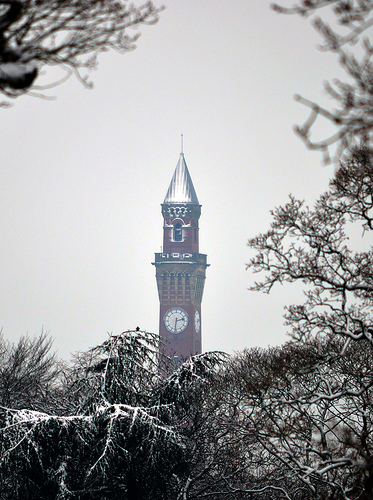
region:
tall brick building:
[140, 123, 217, 378]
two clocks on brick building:
[161, 308, 199, 339]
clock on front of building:
[157, 304, 190, 341]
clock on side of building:
[193, 307, 202, 336]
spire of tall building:
[156, 152, 203, 205]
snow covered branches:
[1, 339, 248, 499]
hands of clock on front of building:
[168, 315, 190, 334]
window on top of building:
[167, 219, 185, 250]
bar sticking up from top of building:
[179, 131, 185, 153]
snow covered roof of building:
[156, 151, 207, 198]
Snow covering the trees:
[19, 332, 244, 475]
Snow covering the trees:
[306, 254, 371, 444]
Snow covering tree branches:
[18, 377, 362, 470]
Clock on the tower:
[160, 301, 193, 331]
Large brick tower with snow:
[136, 178, 229, 337]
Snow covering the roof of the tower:
[167, 178, 213, 208]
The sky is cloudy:
[27, 226, 96, 306]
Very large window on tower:
[167, 213, 191, 247]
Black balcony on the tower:
[150, 241, 210, 269]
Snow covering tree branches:
[0, 14, 132, 36]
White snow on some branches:
[14, 392, 183, 459]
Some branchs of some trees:
[6, 353, 236, 499]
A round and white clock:
[161, 307, 190, 335]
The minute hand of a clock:
[173, 317, 178, 331]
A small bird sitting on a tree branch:
[131, 323, 142, 335]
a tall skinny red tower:
[143, 128, 216, 383]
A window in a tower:
[170, 219, 185, 242]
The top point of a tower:
[172, 131, 192, 159]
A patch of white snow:
[109, 401, 127, 416]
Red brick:
[165, 240, 192, 253]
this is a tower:
[145, 156, 215, 335]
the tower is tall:
[140, 134, 210, 339]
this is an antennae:
[173, 127, 188, 148]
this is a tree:
[81, 369, 287, 484]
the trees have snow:
[46, 365, 173, 460]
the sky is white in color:
[30, 144, 133, 276]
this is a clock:
[163, 306, 189, 331]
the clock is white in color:
[160, 306, 188, 329]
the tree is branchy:
[235, 397, 339, 481]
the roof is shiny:
[174, 172, 186, 192]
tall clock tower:
[148, 131, 211, 355]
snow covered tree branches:
[98, 391, 184, 435]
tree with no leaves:
[6, 341, 51, 398]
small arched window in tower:
[171, 218, 183, 244]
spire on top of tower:
[178, 131, 186, 153]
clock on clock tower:
[163, 306, 189, 333]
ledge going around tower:
[149, 261, 211, 267]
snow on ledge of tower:
[182, 220, 193, 231]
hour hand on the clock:
[173, 314, 186, 323]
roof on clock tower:
[158, 151, 201, 202]